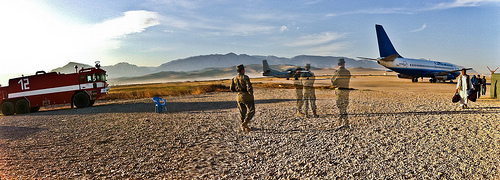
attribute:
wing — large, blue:
[371, 24, 499, 88]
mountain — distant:
[142, 49, 280, 79]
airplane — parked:
[344, 13, 475, 100]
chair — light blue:
[141, 90, 178, 124]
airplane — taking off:
[247, 48, 322, 84]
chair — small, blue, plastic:
[149, 95, 170, 113]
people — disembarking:
[444, 62, 492, 113]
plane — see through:
[337, 29, 497, 143]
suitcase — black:
[452, 92, 461, 103]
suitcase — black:
[467, 88, 478, 100]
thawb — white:
[449, 74, 473, 103]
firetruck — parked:
[2, 59, 110, 116]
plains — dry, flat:
[93, 66, 230, 171]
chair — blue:
[152, 96, 169, 113]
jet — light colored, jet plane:
[362, 21, 472, 79]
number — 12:
[11, 79, 31, 97]